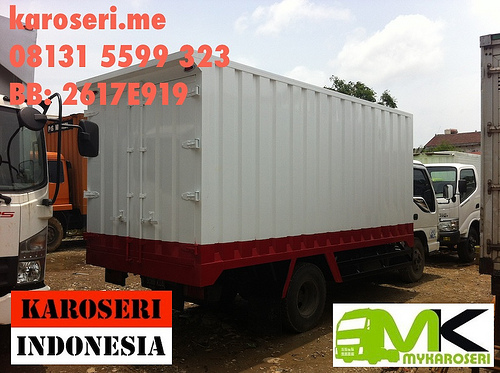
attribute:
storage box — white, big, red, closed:
[78, 51, 414, 244]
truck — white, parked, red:
[412, 158, 440, 256]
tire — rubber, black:
[281, 265, 328, 328]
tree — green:
[324, 77, 396, 105]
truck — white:
[438, 149, 492, 242]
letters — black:
[22, 297, 161, 321]